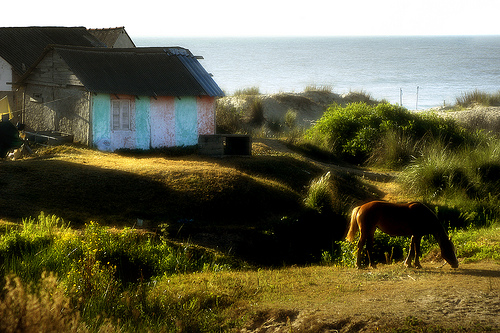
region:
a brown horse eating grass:
[338, 191, 472, 283]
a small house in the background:
[17, 38, 226, 167]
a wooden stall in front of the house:
[198, 125, 263, 167]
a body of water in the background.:
[238, 20, 430, 92]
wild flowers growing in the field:
[11, 206, 211, 318]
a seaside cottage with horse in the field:
[24, 16, 486, 296]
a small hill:
[45, 144, 303, 280]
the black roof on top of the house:
[48, 37, 230, 110]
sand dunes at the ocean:
[241, 75, 328, 130]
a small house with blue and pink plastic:
[13, 45, 235, 170]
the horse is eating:
[337, 178, 469, 276]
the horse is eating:
[340, 210, 415, 307]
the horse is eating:
[351, 186, 497, 319]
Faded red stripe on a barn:
[148, 97, 175, 145]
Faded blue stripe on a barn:
[171, 95, 198, 147]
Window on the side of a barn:
[109, 97, 133, 130]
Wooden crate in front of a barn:
[199, 130, 254, 158]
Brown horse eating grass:
[342, 200, 466, 275]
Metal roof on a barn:
[171, 47, 231, 100]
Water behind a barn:
[224, 46, 495, 90]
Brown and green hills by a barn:
[3, 150, 381, 330]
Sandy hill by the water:
[426, 103, 499, 125]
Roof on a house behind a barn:
[1, 29, 143, 67]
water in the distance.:
[345, 48, 426, 63]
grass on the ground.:
[335, 297, 392, 309]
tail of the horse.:
[342, 200, 355, 241]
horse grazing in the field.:
[401, 195, 478, 267]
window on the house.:
[108, 99, 130, 129]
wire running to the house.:
[9, 92, 68, 122]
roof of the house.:
[103, 59, 175, 89]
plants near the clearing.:
[73, 268, 117, 318]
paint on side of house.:
[160, 109, 185, 136]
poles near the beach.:
[410, 85, 425, 110]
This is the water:
[202, 23, 498, 115]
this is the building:
[21, 35, 206, 161]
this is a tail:
[335, 195, 362, 240]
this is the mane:
[418, 200, 454, 252]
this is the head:
[435, 237, 465, 271]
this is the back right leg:
[353, 220, 370, 275]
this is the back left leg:
[362, 228, 384, 270]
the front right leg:
[403, 226, 432, 279]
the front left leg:
[407, 225, 426, 263]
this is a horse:
[328, 191, 481, 287]